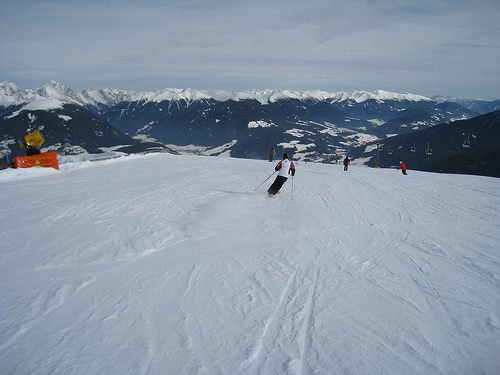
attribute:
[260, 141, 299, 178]
jacket — white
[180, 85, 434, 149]
mountain — covered, blue, here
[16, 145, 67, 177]
sign — orage, yellow, red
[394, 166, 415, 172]
jacket — red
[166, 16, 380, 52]
sky — cloudy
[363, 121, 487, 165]
lift — here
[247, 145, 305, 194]
person — present, here, skiing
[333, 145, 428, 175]
people — skiing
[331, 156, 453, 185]
skiers — skiing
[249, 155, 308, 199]
skier — fourth, here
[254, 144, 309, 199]
tourist — skiing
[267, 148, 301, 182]
coat — white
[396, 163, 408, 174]
coat — red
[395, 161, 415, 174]
shirt — here, red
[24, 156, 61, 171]
netting — orange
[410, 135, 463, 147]
metal — gre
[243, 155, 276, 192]
pole — black